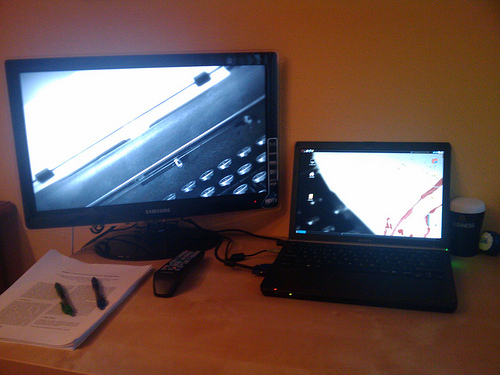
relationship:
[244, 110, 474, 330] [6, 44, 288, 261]
laptop has monitor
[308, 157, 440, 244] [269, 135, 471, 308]
typewriter on laptop monitor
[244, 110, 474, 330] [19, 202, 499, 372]
laptop on desk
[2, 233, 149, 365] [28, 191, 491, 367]
documents on desk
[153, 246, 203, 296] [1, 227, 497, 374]
remote on desk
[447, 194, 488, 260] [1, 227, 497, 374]
beer on desk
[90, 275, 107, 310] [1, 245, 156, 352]
pen on papers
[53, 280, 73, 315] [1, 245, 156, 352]
pen on papers